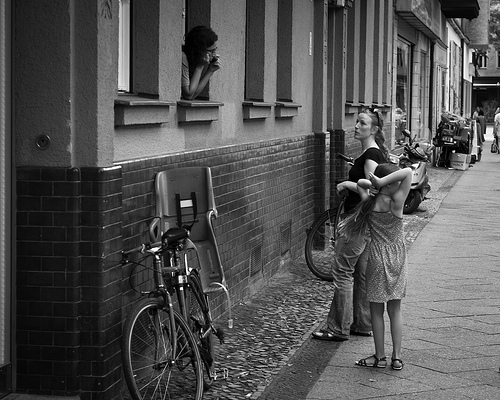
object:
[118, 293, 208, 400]
wheel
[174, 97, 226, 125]
ledge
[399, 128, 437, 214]
scooter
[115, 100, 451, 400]
walk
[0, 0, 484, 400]
building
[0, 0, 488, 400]
building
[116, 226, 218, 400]
bicycle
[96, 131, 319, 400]
wall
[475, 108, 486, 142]
people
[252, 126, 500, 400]
sidewalk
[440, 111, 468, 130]
luggage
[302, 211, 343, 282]
tire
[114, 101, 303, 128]
row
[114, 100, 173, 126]
window sills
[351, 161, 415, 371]
girl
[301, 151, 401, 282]
bicycle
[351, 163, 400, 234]
hair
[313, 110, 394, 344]
lady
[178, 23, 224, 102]
lady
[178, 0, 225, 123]
window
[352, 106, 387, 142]
head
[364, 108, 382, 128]
sunglasses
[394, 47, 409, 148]
door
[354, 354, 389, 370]
sandal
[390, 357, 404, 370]
sandal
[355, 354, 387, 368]
foot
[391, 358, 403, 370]
foot